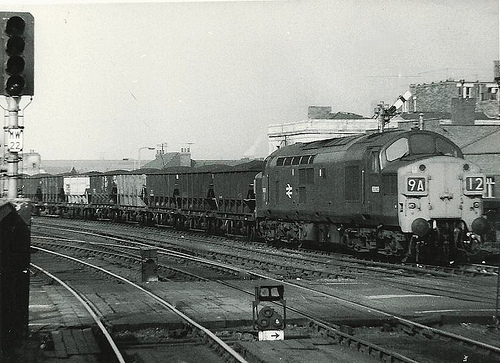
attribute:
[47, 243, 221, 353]
railtracks — metallic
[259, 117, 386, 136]
building top — white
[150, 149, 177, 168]
roof — black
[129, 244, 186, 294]
box — black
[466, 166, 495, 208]
number — 12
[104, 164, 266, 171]
coal — black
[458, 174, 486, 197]
number — white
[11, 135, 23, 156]
number — 22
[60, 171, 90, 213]
train car — white, darker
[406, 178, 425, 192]
9a — white